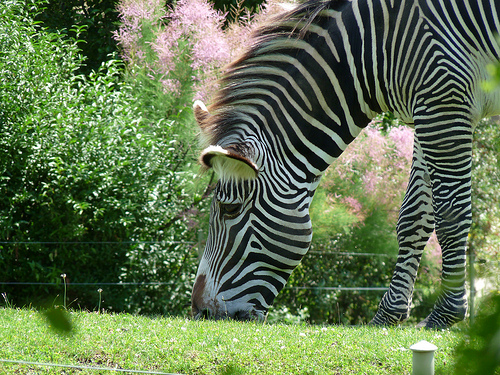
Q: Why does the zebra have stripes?
A: Camoflage.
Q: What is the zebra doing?
A: Grazing.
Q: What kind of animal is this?
A: Zebra.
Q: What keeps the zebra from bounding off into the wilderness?
A: Fence.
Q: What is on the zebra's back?
A: Striped mane.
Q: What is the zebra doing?
A: Grazing.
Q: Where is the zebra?
A: Grass.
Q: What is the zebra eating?
A: Grass.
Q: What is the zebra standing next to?
A: Green bush.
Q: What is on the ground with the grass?
A: Shadows.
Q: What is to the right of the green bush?
A: Lavender bush.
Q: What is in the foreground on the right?
A: Thin white pole in ground.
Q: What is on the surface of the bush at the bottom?
A: Dark shadow.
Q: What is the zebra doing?
A: Eating grass.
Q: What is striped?
A: Zebra.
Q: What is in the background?
A: Pink flowers.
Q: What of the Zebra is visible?
A: Head and front legs.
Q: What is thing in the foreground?
A: Wire.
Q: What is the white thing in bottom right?
A: A pole.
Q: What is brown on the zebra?
A: Nose and tips of ears.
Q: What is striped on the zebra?
A: Hair.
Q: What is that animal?
A: Zebra.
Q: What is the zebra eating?
A: Grass.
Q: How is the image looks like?
A: Good.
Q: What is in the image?
A: Zebra.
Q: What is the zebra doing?
A: Feeding on grass.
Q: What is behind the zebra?
A: Pink vegetation.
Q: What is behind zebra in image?
A: Green thick vegetation.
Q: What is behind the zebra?
A: Mesh fence.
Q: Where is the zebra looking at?
A: Grass.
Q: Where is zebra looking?
A: Grassy field.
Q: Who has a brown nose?
A: A zebra.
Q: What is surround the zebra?
A: Wired Fence.